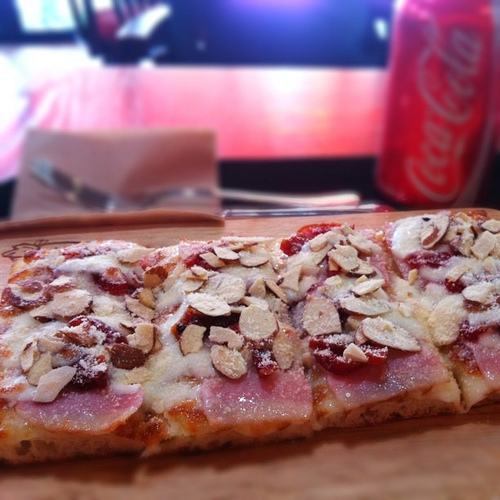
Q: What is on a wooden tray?
A: Bread.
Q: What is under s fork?
A: Napkin.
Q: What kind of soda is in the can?
A: Coca cola.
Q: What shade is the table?
A: Red.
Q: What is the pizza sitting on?
A: A table.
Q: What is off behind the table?
A: Chair.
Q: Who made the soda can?
A: Coca cola.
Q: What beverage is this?
A: Coca Cola.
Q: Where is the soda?
A: Behind the food.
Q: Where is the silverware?
A: On the napkin.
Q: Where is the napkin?
A: Under the silverware.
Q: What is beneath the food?
A: Table.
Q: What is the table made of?
A: Wood.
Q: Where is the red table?
A: Behind soda can.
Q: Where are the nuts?
A: On top of the bacon.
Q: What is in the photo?
A: Pizza.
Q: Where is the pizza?
A: On a table.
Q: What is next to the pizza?
A: A coke.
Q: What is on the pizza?
A: Toppings.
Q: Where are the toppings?
A: On the pizza.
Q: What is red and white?
A: Coke.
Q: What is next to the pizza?
A: Fork.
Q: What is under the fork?
A: Napkin.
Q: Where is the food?
A: Laid out on a flat surface, in front of a fork and a coke can.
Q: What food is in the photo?
A: Pizza.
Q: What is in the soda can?
A: Coca-Cola.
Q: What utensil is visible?
A: Fork.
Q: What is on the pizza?
A: Ham and almonds.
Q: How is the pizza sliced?
A: Square.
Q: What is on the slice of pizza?
A: The square ham.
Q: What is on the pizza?
A: Almond-looking condiment.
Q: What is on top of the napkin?
A: The silver fork.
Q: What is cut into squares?
A: The pizza bread crusts.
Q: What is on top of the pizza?
A: The powdered cheese.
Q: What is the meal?
A: Pizza and soda.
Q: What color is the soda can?
A: Red.